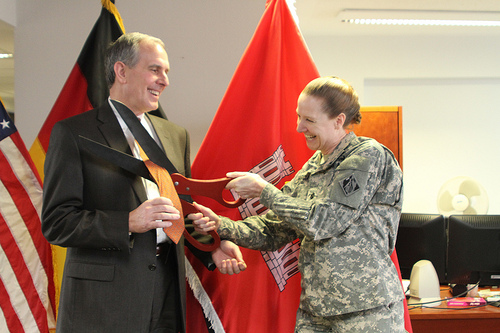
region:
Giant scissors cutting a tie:
[50, 82, 257, 253]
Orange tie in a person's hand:
[126, 140, 185, 239]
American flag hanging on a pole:
[3, 99, 50, 325]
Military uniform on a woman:
[238, 82, 403, 305]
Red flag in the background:
[171, 14, 411, 324]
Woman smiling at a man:
[284, 85, 341, 145]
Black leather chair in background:
[442, 210, 485, 282]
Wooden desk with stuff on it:
[443, 279, 487, 324]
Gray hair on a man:
[96, 29, 169, 107]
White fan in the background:
[416, 171, 484, 222]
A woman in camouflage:
[190, 74, 403, 331]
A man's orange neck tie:
[135, 140, 183, 245]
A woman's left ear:
[334, 110, 347, 130]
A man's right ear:
[113, 60, 126, 82]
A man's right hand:
[127, 196, 179, 232]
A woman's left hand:
[225, 170, 268, 204]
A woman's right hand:
[185, 199, 217, 236]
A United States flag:
[0, 99, 45, 331]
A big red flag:
[187, 0, 416, 332]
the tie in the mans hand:
[143, 160, 186, 246]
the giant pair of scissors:
[78, 134, 250, 254]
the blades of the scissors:
[77, 99, 169, 184]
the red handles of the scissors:
[173, 170, 240, 260]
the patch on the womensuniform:
[327, 152, 380, 213]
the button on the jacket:
[147, 259, 157, 274]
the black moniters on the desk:
[398, 211, 498, 258]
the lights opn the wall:
[340, 5, 497, 35]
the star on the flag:
[0, 114, 14, 130]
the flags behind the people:
[0, 0, 45, 322]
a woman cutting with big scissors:
[180, 56, 424, 322]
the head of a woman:
[295, 74, 355, 148]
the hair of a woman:
[310, 80, 369, 118]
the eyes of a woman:
[288, 108, 320, 125]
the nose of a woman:
[287, 119, 307, 136]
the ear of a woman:
[330, 110, 351, 132]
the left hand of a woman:
[220, 167, 264, 201]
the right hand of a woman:
[187, 204, 219, 229]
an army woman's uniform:
[285, 157, 412, 322]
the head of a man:
[99, 33, 166, 124]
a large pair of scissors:
[55, 83, 295, 290]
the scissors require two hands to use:
[62, 77, 320, 265]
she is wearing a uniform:
[208, 50, 450, 325]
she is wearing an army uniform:
[194, 45, 446, 330]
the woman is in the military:
[201, 38, 430, 328]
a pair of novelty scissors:
[52, 90, 280, 273]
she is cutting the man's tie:
[2, 16, 430, 331]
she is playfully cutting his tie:
[24, 13, 419, 330]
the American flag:
[2, 105, 71, 330]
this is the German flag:
[22, 2, 150, 203]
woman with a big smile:
[291, 78, 358, 155]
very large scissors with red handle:
[74, 103, 250, 256]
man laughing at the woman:
[121, 30, 166, 111]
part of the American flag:
[0, 114, 40, 321]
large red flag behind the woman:
[244, 68, 294, 168]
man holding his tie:
[134, 172, 187, 243]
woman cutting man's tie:
[57, 93, 396, 246]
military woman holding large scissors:
[77, 71, 407, 331]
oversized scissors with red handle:
[76, 98, 248, 254]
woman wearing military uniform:
[187, 73, 408, 331]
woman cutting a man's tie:
[74, 74, 413, 331]